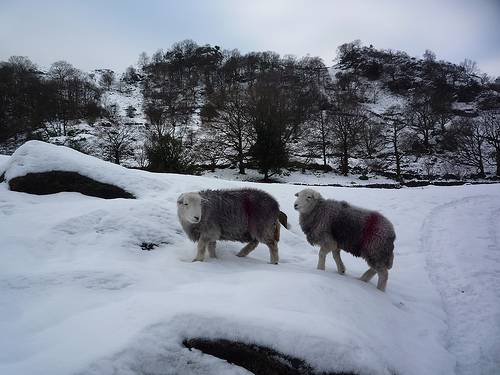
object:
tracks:
[421, 193, 500, 375]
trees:
[0, 38, 497, 181]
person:
[326, 140, 331, 144]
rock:
[0, 168, 136, 198]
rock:
[1, 140, 161, 200]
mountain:
[0, 49, 500, 189]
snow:
[0, 51, 500, 375]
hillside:
[0, 62, 499, 187]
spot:
[241, 193, 255, 231]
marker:
[359, 211, 379, 250]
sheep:
[177, 187, 396, 292]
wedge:
[179, 338, 352, 375]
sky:
[0, 0, 500, 81]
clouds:
[0, 0, 498, 82]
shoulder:
[203, 192, 217, 219]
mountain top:
[331, 46, 477, 77]